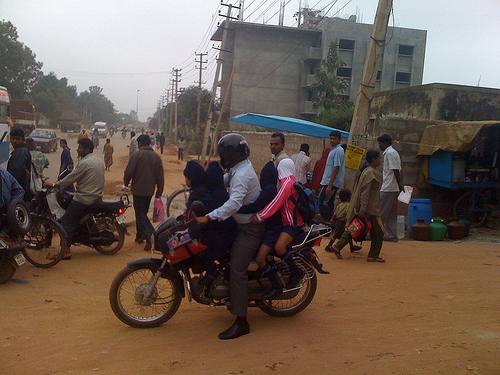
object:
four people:
[182, 130, 306, 340]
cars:
[28, 129, 58, 153]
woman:
[330, 149, 386, 263]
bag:
[346, 216, 371, 242]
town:
[0, 0, 500, 375]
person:
[123, 134, 165, 251]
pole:
[172, 69, 182, 144]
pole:
[194, 53, 209, 133]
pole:
[200, 1, 243, 166]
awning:
[228, 111, 350, 139]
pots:
[412, 219, 471, 241]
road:
[0, 128, 500, 375]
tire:
[108, 264, 184, 329]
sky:
[0, 0, 195, 77]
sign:
[344, 143, 366, 171]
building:
[210, 7, 431, 134]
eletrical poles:
[344, 0, 396, 191]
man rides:
[109, 132, 333, 340]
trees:
[0, 21, 121, 127]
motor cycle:
[109, 201, 334, 328]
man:
[192, 133, 265, 341]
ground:
[0, 253, 500, 375]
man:
[43, 137, 105, 260]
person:
[376, 134, 406, 243]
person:
[329, 150, 386, 263]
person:
[317, 130, 347, 221]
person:
[175, 137, 187, 161]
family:
[182, 133, 306, 340]